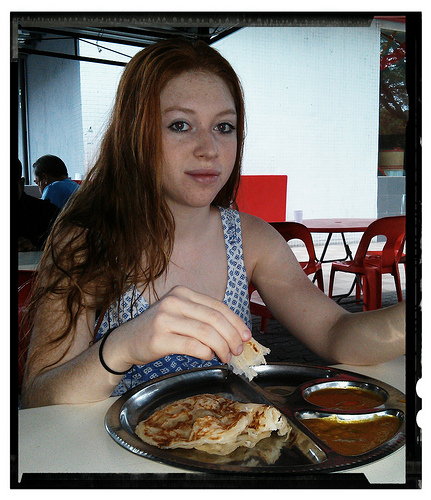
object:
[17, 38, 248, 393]
hair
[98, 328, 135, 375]
hair band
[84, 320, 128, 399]
wrist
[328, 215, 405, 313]
chair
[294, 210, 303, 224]
cup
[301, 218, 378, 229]
table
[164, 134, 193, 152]
freckles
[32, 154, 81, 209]
man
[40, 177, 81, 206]
shirt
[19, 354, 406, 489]
table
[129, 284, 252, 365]
hand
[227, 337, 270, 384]
food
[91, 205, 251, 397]
blouse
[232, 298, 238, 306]
design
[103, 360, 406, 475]
tray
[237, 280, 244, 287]
design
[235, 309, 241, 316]
design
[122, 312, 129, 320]
design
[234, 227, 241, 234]
design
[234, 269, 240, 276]
design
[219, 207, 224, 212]
design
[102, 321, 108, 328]
design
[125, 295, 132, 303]
design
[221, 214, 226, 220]
design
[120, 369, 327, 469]
section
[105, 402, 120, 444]
edge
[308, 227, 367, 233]
edge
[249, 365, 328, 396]
section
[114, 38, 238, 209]
head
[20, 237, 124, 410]
arm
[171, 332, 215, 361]
finger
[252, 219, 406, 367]
arm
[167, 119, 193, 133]
eye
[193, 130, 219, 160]
nose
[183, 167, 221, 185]
mouth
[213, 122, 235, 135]
eye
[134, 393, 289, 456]
bread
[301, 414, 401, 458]
sauce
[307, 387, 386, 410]
sauce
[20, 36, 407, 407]
wall